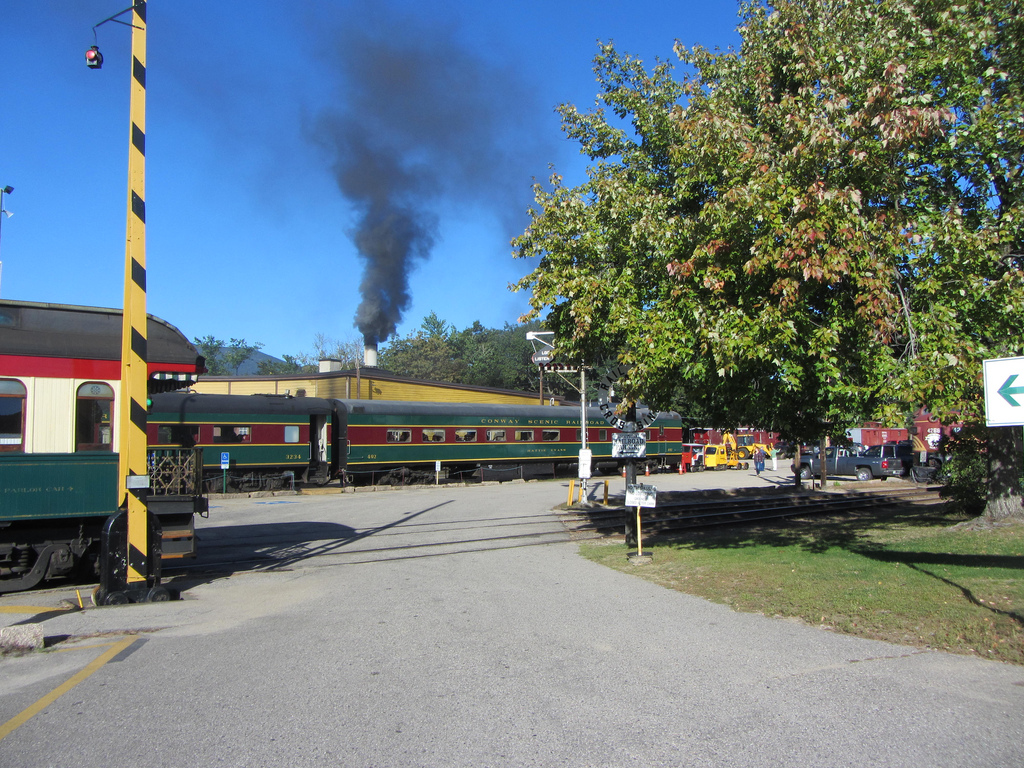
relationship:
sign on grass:
[984, 395, 991, 424] [645, 477, 991, 661]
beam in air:
[79, 16, 186, 611] [10, 32, 879, 618]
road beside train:
[15, 447, 1016, 763] [0, 299, 709, 594]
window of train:
[195, 417, 250, 454] [91, 365, 705, 491]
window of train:
[385, 421, 433, 469] [91, 365, 705, 491]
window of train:
[426, 421, 481, 461] [140, 384, 717, 499]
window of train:
[449, 410, 489, 450] [117, 380, 701, 487]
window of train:
[475, 417, 534, 472] [125, 380, 735, 514]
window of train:
[508, 421, 537, 454] [140, 384, 717, 499]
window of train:
[534, 414, 571, 451] [132, 373, 709, 480]